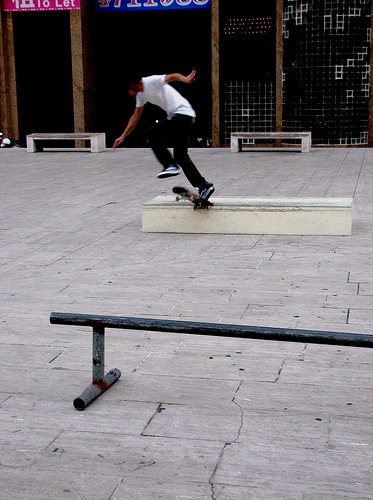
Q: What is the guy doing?
A: Skateboarding.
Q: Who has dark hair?
A: Skateboarder.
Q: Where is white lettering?
A: On red sign.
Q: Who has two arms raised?
A: The skateboarder.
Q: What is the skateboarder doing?
A: Performing a trick.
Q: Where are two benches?
A: Near the building.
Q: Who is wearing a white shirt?
A: Guy skateboarding.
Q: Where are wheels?
A: On the skateboard.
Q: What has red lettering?
A: Blue sign.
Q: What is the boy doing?
A: Skateboarding.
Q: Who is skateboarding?
A: The boy.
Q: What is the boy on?
A: Skateboard.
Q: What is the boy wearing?
A: White shirt.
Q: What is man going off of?
A: Jump.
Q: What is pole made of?
A: Metal.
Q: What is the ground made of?
A: Cement.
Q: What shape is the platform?
A: Rectangular.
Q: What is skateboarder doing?
A: Trick.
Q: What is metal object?
A: Pole.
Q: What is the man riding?
A: A skateboard.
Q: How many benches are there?
A: 2.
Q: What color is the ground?
A: Gray.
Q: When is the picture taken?
A: Daytime.